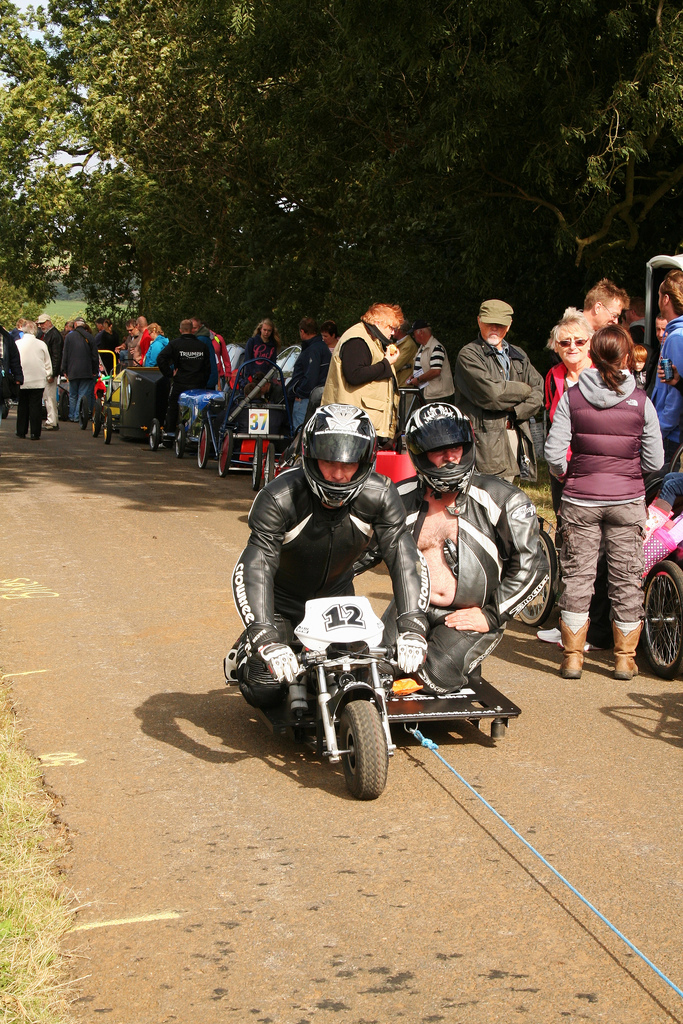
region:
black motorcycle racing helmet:
[299, 401, 381, 509]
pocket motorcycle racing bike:
[289, 592, 408, 800]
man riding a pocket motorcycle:
[224, 401, 431, 799]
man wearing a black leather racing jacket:
[390, 474, 549, 693]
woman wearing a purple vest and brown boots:
[544, 322, 664, 678]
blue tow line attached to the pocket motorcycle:
[404, 721, 681, 1021]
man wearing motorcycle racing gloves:
[395, 610, 429, 675]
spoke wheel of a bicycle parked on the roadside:
[640, 559, 681, 679]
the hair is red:
[363, 303, 403, 332]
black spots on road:
[361, 960, 409, 995]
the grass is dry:
[0, 746, 84, 1023]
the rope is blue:
[411, 730, 681, 999]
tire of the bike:
[338, 702, 385, 797]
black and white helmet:
[306, 401, 375, 505]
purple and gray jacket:
[542, 373, 664, 501]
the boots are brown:
[560, 622, 640, 678]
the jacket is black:
[155, 334, 216, 390]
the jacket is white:
[17, 336, 52, 387]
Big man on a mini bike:
[231, 402, 430, 796]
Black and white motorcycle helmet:
[301, 401, 378, 508]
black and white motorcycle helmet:
[403, 403, 478, 488]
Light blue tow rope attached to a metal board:
[410, 729, 681, 1000]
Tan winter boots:
[561, 617, 636, 678]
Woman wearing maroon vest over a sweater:
[546, 326, 666, 675]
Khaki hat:
[478, 299, 514, 328]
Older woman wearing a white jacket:
[17, 321, 52, 439]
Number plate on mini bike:
[295, 592, 383, 650]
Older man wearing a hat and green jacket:
[456, 298, 545, 487]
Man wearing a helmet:
[292, 394, 382, 514]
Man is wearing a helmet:
[296, 400, 378, 515]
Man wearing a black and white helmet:
[293, 394, 389, 513]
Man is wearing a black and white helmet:
[287, 395, 381, 516]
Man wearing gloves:
[245, 624, 442, 688]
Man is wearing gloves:
[253, 622, 421, 682]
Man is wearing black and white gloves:
[247, 620, 441, 688]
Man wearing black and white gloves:
[259, 624, 429, 691]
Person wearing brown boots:
[547, 608, 651, 691]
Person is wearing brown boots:
[550, 609, 649, 685]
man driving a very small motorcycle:
[231, 401, 423, 798]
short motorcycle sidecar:
[378, 659, 521, 746]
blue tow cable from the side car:
[409, 728, 681, 992]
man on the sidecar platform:
[381, 403, 526, 696]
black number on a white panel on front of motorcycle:
[293, 597, 385, 647]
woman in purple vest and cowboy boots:
[540, 326, 661, 677]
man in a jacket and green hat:
[454, 296, 545, 478]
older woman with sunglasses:
[544, 306, 592, 403]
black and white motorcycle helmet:
[298, 407, 377, 506]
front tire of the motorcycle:
[337, 704, 388, 796]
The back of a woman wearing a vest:
[544, 322, 664, 512]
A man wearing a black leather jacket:
[391, 400, 556, 647]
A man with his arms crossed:
[448, 294, 545, 425]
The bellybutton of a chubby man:
[429, 584, 448, 602]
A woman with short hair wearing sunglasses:
[544, 306, 594, 361]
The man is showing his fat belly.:
[401, 497, 473, 620]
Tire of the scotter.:
[342, 696, 389, 798]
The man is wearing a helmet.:
[304, 403, 363, 490]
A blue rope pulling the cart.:
[416, 719, 536, 846]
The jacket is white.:
[21, 341, 54, 380]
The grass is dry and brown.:
[13, 813, 86, 1003]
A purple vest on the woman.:
[564, 388, 656, 497]